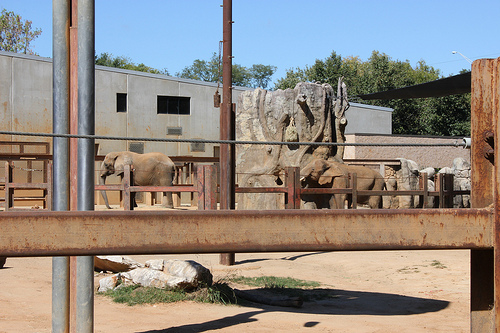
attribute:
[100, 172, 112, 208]
trunk — long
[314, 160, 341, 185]
ear — large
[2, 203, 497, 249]
pole — Metal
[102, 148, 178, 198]
elephant — male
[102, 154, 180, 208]
elephants — grown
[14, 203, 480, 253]
bar — rusted, metal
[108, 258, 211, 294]
rock — tan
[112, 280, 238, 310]
grass — patch of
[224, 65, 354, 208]
rock structure — large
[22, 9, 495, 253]
iron fences — around